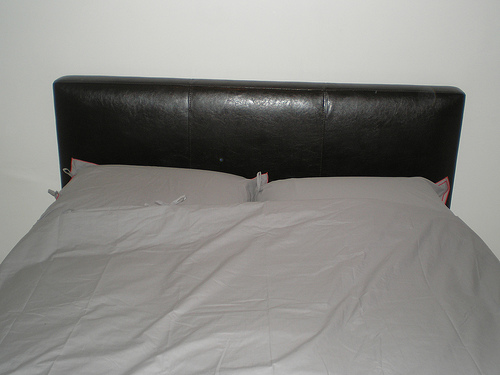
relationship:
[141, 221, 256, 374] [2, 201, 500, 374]
wrinkles are on a bedsheet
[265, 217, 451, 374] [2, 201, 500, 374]
wrinkles are on a bedsheet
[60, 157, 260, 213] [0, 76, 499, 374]
pillow on bed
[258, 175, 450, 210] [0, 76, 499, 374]
pillow are on a bed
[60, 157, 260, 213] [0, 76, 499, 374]
pillow on a bed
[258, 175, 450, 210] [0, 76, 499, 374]
pillow on a bed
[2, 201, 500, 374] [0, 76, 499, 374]
bedsheet on bed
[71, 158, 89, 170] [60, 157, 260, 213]
corner on pillow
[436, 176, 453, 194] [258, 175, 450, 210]
corner on pillow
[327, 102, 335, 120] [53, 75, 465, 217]
wrinkle on head board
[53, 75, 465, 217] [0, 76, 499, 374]
head board on bed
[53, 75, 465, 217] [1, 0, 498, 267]
head board against wall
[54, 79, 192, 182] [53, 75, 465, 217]
section on head board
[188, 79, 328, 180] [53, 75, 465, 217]
section on head board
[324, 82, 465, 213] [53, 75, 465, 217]
section on head board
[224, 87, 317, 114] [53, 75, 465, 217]
reflection on head board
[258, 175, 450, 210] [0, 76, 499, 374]
pillow on bed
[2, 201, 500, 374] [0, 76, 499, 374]
bedsheet covering bed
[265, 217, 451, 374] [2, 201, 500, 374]
wrinkles are on bedsheet